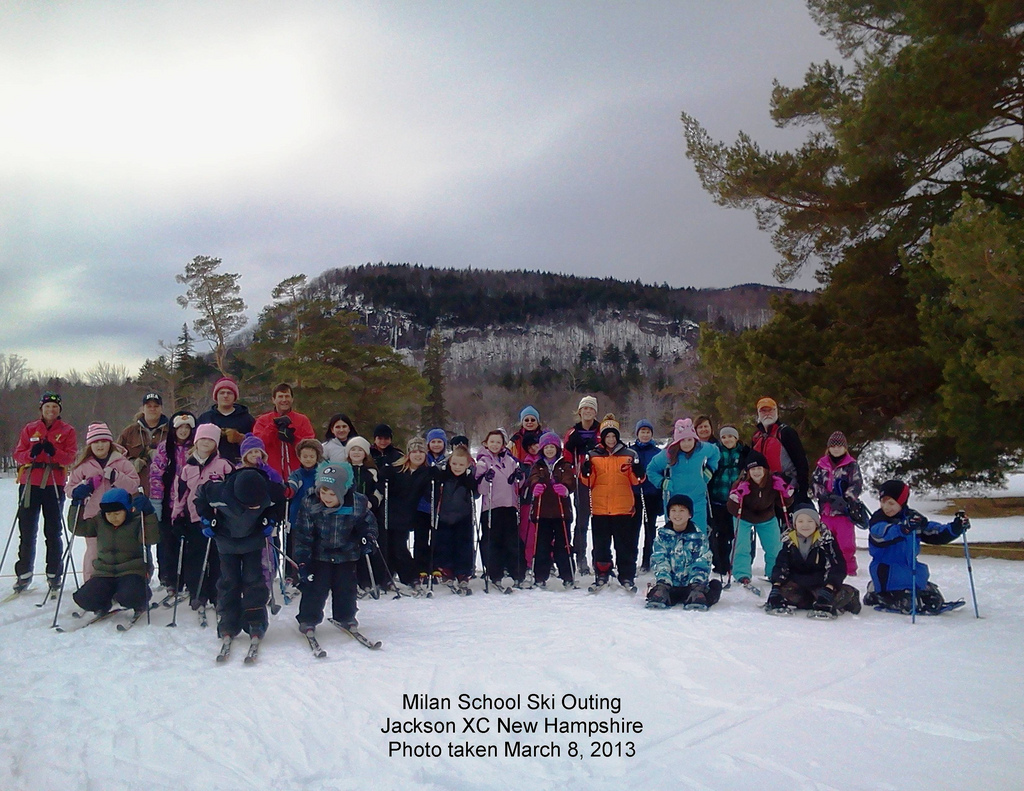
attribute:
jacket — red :
[17, 421, 81, 479]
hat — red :
[210, 372, 239, 396]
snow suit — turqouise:
[646, 438, 720, 538]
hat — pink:
[669, 415, 698, 441]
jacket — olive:
[65, 500, 155, 583]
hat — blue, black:
[96, 485, 132, 511]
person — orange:
[571, 412, 645, 593]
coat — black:
[573, 447, 647, 514]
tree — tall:
[906, 188, 1023, 483]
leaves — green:
[879, 286, 947, 350]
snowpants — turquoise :
[728, 516, 787, 599]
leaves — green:
[262, 312, 368, 383]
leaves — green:
[854, 280, 886, 320]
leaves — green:
[690, 121, 861, 243]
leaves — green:
[700, 136, 830, 223]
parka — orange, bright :
[546, 422, 715, 582]